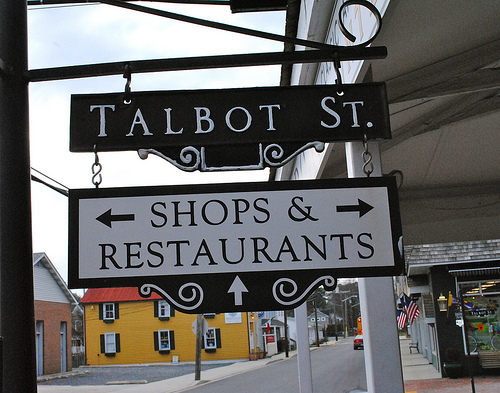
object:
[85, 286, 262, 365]
building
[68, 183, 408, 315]
signs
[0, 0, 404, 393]
sign holder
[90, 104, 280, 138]
writing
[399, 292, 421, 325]
flags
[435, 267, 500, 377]
shops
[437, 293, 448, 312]
lantern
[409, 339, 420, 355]
bench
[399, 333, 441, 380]
sidewalk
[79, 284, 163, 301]
roof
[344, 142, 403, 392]
pole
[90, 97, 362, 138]
talbot st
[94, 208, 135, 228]
arrow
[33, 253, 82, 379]
building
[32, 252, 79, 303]
roof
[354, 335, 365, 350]
car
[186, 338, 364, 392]
road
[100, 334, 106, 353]
shutters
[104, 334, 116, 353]
window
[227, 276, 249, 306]
arrow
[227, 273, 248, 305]
up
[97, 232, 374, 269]
restaurants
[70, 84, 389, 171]
signage